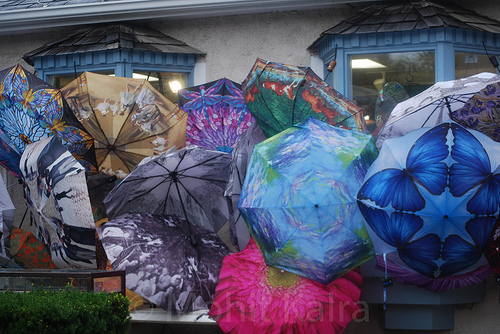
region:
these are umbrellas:
[3, 51, 498, 315]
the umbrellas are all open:
[1, 45, 498, 314]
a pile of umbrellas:
[7, 50, 497, 310]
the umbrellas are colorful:
[1, 50, 498, 325]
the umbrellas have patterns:
[0, 40, 496, 331]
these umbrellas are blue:
[240, 113, 499, 287]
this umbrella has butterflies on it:
[362, 129, 497, 295]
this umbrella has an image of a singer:
[99, 199, 239, 314]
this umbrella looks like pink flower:
[202, 242, 370, 330]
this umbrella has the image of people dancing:
[76, 71, 195, 181]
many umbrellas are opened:
[68, 28, 497, 266]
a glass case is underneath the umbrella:
[10, 255, 172, 289]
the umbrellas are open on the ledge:
[359, 274, 426, 317]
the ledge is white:
[137, 295, 242, 327]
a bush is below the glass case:
[17, 260, 69, 311]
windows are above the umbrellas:
[311, 35, 498, 157]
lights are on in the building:
[342, 45, 394, 72]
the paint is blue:
[35, 56, 174, 96]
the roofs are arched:
[41, 25, 248, 90]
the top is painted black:
[77, 24, 177, 70]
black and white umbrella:
[17, 133, 101, 275]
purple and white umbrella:
[98, 205, 235, 314]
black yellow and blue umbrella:
[3, 63, 100, 189]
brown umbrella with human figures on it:
[59, 65, 189, 186]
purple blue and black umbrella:
[171, 74, 261, 156]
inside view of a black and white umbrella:
[101, 140, 241, 229]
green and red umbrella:
[238, 53, 373, 140]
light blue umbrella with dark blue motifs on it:
[351, 120, 498, 282]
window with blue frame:
[305, 28, 499, 139]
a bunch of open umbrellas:
[3, 55, 497, 332]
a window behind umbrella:
[304, 36, 498, 287]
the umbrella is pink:
[208, 271, 365, 331]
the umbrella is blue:
[355, 125, 496, 301]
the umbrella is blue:
[0, 60, 70, 145]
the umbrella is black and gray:
[16, 125, 107, 276]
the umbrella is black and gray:
[97, 137, 237, 237]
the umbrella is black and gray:
[95, 206, 216, 311]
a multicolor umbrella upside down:
[233, 51, 370, 136]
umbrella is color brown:
[63, 67, 191, 173]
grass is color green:
[0, 277, 134, 331]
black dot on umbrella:
[434, 201, 459, 228]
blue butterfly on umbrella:
[377, 163, 443, 200]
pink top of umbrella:
[235, 293, 267, 316]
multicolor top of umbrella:
[286, 158, 328, 187]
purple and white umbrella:
[139, 237, 172, 269]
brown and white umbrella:
[98, 88, 135, 120]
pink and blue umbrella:
[200, 96, 230, 134]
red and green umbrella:
[271, 87, 297, 109]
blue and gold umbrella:
[14, 89, 58, 119]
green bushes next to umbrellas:
[28, 300, 94, 327]